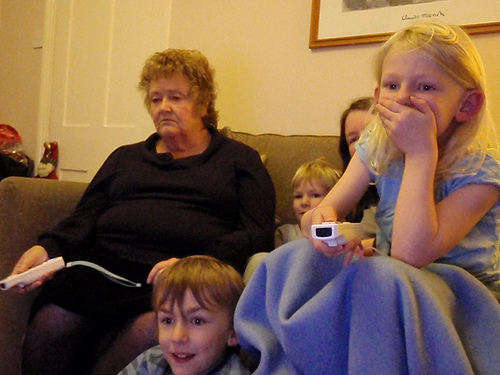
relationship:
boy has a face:
[113, 252, 253, 374] [161, 279, 214, 373]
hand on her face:
[376, 96, 440, 154] [381, 45, 464, 143]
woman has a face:
[2, 49, 277, 374] [149, 75, 194, 136]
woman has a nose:
[2, 49, 277, 374] [159, 99, 170, 114]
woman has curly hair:
[2, 49, 277, 374] [136, 50, 219, 128]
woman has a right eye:
[2, 49, 277, 374] [150, 95, 164, 105]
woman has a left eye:
[2, 49, 277, 374] [170, 93, 183, 99]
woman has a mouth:
[2, 49, 277, 374] [159, 118, 178, 126]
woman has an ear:
[2, 49, 277, 374] [197, 93, 210, 115]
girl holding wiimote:
[234, 20, 500, 374] [310, 221, 362, 247]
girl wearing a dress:
[234, 20, 500, 374] [356, 139, 500, 297]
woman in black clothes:
[2, 49, 277, 374] [34, 132, 277, 323]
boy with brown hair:
[113, 252, 253, 374] [155, 253, 245, 321]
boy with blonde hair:
[274, 155, 344, 247] [292, 155, 343, 190]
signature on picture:
[401, 9, 445, 22] [319, 1, 500, 43]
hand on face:
[376, 96, 440, 154] [381, 45, 464, 143]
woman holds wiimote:
[2, 49, 277, 374] [0, 253, 67, 291]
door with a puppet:
[36, 2, 174, 177] [34, 139, 60, 179]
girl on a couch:
[234, 20, 500, 374] [0, 121, 344, 374]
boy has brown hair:
[113, 252, 253, 374] [155, 253, 245, 321]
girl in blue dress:
[234, 20, 500, 374] [356, 139, 500, 297]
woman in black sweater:
[2, 49, 277, 374] [34, 122, 277, 268]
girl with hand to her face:
[234, 20, 500, 374] [381, 45, 464, 143]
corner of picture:
[310, 29, 328, 47] [319, 1, 500, 43]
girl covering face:
[234, 20, 500, 374] [381, 45, 464, 143]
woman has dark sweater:
[2, 49, 277, 374] [34, 122, 277, 268]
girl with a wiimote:
[234, 20, 500, 374] [310, 221, 362, 247]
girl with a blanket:
[234, 20, 500, 374] [234, 236, 499, 374]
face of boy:
[161, 279, 214, 373] [113, 252, 253, 374]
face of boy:
[294, 188, 322, 207] [274, 155, 344, 247]